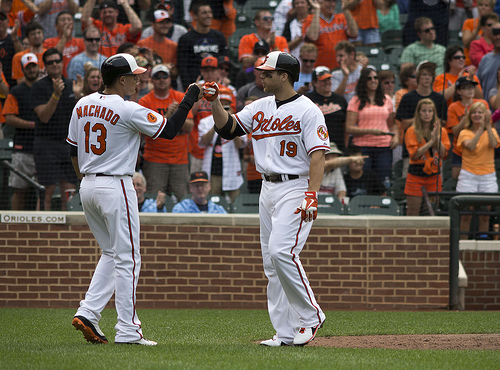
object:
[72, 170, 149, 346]
pants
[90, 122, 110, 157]
number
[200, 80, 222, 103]
hands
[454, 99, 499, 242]
woman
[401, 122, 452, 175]
orange shirt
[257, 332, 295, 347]
shoe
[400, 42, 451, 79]
shirt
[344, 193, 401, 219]
chair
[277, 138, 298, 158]
number 19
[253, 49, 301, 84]
cap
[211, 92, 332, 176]
baseball jersey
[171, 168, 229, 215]
man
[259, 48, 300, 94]
head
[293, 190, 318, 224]
glove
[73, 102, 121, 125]
name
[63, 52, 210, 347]
baseball player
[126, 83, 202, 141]
black sleeves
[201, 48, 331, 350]
baseball player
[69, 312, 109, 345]
shoe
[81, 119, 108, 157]
number 13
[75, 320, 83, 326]
cleat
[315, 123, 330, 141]
logo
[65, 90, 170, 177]
jersey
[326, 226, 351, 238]
brick wall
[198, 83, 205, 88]
knuckle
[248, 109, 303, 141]
orioles print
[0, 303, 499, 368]
field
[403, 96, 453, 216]
audience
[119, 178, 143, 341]
stripe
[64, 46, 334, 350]
touching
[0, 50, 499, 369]
baseball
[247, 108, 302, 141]
orioles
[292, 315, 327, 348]
foot